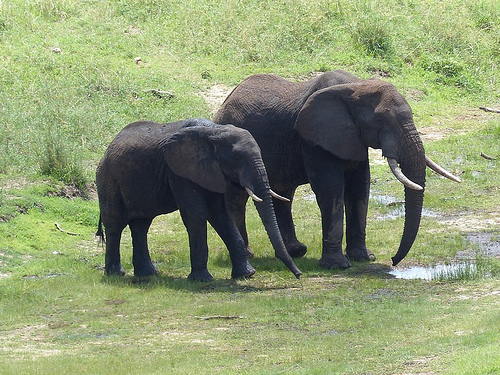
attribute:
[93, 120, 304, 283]
baby elephant — small, gray, standing, dark gray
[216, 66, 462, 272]
elephant — walking, gray, large, outdoors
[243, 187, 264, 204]
tusk — white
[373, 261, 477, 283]
puddle — reflective, small, water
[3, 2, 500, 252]
hill — grassy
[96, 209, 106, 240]
tail — small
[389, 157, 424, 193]
tusk — large, white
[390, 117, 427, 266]
trunk — long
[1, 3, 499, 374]
grass — green, long, dry, rough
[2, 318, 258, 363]
dirt — light brown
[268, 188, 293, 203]
tusk — white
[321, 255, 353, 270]
foot — large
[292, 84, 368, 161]
ear — gigantic